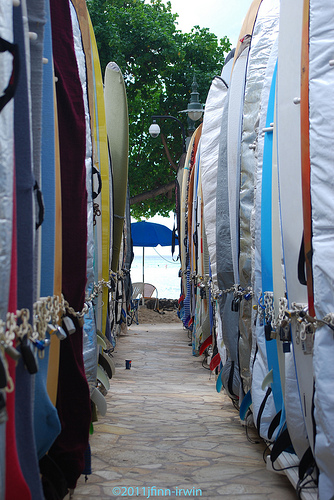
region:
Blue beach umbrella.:
[127, 221, 178, 247]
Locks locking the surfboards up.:
[1, 263, 328, 373]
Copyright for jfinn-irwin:
[109, 484, 206, 499]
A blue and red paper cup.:
[125, 356, 132, 368]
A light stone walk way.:
[82, 317, 292, 497]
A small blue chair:
[128, 296, 140, 325]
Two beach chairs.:
[133, 279, 161, 314]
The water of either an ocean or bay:
[135, 251, 179, 300]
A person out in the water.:
[162, 262, 169, 268]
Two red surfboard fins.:
[197, 334, 221, 374]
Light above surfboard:
[178, 66, 205, 126]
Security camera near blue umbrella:
[147, 110, 185, 149]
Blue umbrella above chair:
[131, 217, 178, 307]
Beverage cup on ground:
[123, 358, 133, 371]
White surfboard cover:
[198, 72, 227, 341]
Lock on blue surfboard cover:
[50, 321, 67, 344]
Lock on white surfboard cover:
[303, 322, 315, 337]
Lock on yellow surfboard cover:
[62, 311, 77, 338]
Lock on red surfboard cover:
[13, 332, 37, 375]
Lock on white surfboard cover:
[268, 326, 276, 340]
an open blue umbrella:
[117, 214, 179, 267]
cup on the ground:
[111, 350, 133, 387]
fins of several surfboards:
[75, 338, 121, 455]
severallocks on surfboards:
[225, 315, 328, 345]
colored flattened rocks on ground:
[107, 403, 236, 482]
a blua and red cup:
[117, 355, 138, 375]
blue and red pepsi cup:
[101, 347, 145, 390]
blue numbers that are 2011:
[110, 480, 149, 498]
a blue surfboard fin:
[220, 387, 261, 426]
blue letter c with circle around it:
[107, 480, 123, 498]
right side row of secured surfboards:
[167, 0, 332, 493]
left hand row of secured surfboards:
[1, 1, 141, 497]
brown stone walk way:
[69, 311, 309, 498]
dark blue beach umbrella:
[119, 213, 180, 255]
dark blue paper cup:
[120, 356, 135, 371]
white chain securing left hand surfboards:
[0, 258, 130, 358]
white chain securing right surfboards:
[178, 264, 331, 357]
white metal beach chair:
[131, 280, 156, 307]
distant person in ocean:
[161, 262, 171, 273]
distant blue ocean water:
[129, 251, 180, 291]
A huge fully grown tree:
[83, 0, 233, 218]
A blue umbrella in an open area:
[127, 219, 175, 303]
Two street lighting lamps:
[144, 66, 201, 136]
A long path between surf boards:
[56, 321, 294, 494]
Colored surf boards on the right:
[174, 0, 328, 497]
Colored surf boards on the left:
[0, 0, 132, 497]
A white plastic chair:
[129, 277, 156, 308]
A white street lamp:
[146, 113, 185, 151]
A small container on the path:
[122, 356, 130, 367]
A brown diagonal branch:
[129, 176, 178, 210]